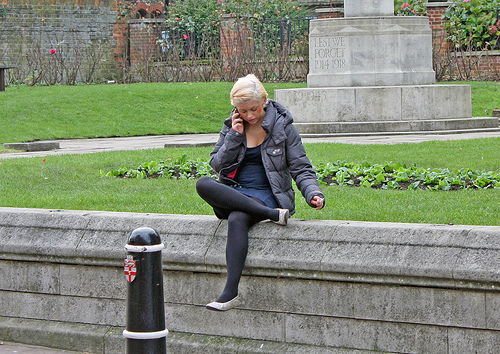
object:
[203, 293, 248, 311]
flats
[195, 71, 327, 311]
woman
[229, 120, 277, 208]
shirt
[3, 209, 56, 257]
wall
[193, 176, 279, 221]
stockings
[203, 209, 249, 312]
legs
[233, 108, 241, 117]
phone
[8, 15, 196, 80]
shrubs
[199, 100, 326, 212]
jacket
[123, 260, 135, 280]
red cross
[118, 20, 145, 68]
columns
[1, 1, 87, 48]
wall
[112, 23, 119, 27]
brick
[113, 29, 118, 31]
brick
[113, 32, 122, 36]
brick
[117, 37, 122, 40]
brick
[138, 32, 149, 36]
brick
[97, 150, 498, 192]
crops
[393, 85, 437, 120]
wall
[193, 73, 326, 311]
girl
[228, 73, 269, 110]
hair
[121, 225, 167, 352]
cigarette post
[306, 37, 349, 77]
letters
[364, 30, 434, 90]
concrete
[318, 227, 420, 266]
concrete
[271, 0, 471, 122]
statue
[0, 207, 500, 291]
ledge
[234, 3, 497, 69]
shrubs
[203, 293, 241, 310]
feet